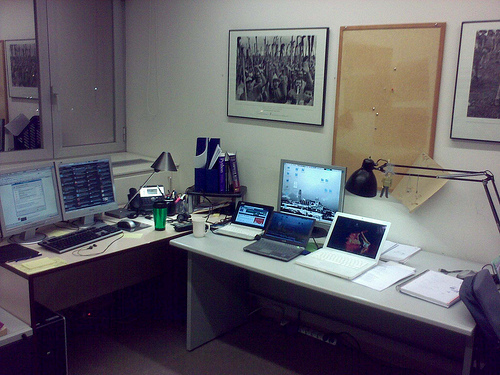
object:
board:
[330, 21, 446, 192]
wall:
[123, 0, 499, 263]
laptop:
[242, 208, 316, 262]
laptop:
[294, 212, 394, 283]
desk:
[168, 211, 496, 374]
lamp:
[340, 157, 378, 201]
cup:
[151, 199, 167, 232]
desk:
[1, 204, 239, 349]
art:
[223, 26, 329, 128]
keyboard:
[36, 221, 125, 253]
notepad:
[395, 268, 464, 314]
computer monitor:
[275, 158, 345, 230]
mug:
[189, 213, 210, 239]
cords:
[337, 331, 361, 355]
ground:
[57, 271, 468, 373]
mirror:
[0, 2, 40, 155]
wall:
[1, 0, 123, 213]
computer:
[0, 161, 64, 255]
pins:
[388, 65, 399, 71]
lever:
[49, 90, 59, 108]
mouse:
[118, 219, 139, 230]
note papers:
[21, 255, 61, 275]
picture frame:
[223, 24, 329, 127]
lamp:
[104, 151, 177, 220]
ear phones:
[70, 230, 126, 258]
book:
[226, 151, 242, 191]